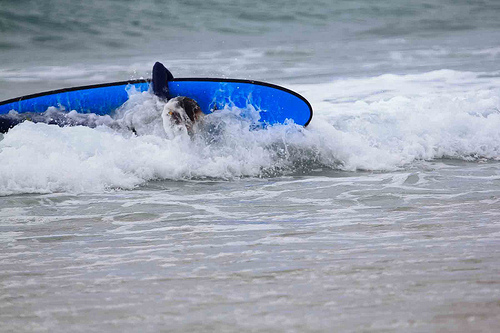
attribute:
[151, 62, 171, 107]
shirt — blue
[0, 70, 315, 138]
surfboard — blue, black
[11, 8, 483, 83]
water — body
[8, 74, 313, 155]
surfboard — on its' side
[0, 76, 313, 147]
surfboard — blue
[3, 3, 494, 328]
waves — rough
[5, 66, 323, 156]
surfboard — blue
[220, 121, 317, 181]
ocean wave — small, white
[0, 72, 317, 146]
board — black bordered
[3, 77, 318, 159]
surfboard — blue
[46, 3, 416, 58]
clouds — white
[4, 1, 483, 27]
sky — blue